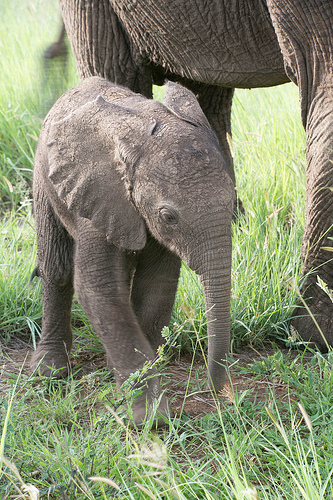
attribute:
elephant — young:
[24, 78, 244, 356]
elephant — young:
[9, 71, 253, 370]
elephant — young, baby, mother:
[25, 70, 240, 422]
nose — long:
[187, 241, 235, 390]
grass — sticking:
[42, 360, 316, 461]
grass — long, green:
[252, 97, 299, 198]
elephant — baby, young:
[29, 78, 240, 390]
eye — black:
[154, 203, 178, 228]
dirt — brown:
[0, 335, 331, 465]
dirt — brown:
[1, 331, 252, 451]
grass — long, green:
[79, 395, 322, 492]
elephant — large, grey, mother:
[35, 66, 259, 398]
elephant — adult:
[42, 0, 332, 350]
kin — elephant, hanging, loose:
[285, 39, 317, 133]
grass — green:
[1, 0, 332, 499]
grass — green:
[4, 95, 329, 474]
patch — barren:
[8, 346, 310, 435]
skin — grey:
[199, 20, 257, 61]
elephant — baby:
[13, 68, 248, 330]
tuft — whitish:
[98, 399, 147, 451]